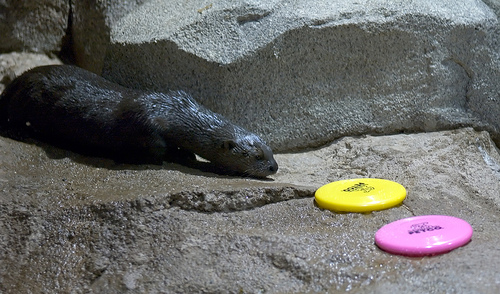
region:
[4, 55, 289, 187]
A sea otter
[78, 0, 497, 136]
A large boulder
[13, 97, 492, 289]
A large boulder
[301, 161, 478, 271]
A pair of frisbees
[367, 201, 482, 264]
A pink frisbee on the boulder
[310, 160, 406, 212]
A yellow frisbee on the boulder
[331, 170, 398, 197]
branding on the yellow frisbee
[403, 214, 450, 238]
branding on the pink frisbee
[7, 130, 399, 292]
some water on the boulder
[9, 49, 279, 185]
an otter examining some frisbees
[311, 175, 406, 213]
A yellow frisbee with dark writing on top.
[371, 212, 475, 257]
A pink frisbee with purple writing on top.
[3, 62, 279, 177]
Brown otter near a yellow frisbee.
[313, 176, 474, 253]
Yellow and pink frisbee with writing on top.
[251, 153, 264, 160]
Small eye of an otter.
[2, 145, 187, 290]
Large wet brown and gray rock under an otter.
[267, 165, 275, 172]
Black nostril on the side of an otters face.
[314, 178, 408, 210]
Bright yellow frisbee with dark writing on top.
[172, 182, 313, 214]
Large crack in the rock to the left of a yellow frisbee.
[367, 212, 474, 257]
Pink frisbee with purple writing on top.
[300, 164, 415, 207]
yellow plastic frisbee laying on ground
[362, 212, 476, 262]
pink plastic frisbee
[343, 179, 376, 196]
black writing on top of frisbee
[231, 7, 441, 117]
large grey boulder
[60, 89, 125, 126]
wet black fur on side of animal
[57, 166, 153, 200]
grey boulder covered in water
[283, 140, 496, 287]
two frisbees laying on boulder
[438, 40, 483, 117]
large crack in side of boulder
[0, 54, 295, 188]
black animal walking on grey rock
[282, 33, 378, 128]
porous grey rock face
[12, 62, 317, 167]
black wet sea otter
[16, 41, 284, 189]
sea otter in a zoo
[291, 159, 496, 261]
two frisbees on a large rock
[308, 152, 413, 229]
yellow frisbee on large grey rock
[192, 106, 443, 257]
sea otter looking at frisbees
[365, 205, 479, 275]
pink frisbee with purple lettering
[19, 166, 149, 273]
rock wet from sea otter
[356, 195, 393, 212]
light reflecting on frisbee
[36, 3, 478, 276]
large grey rocks in frisbee enclosure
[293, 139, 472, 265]
two frisbees for the sea otter to play with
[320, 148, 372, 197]
yellow frisbee on rocks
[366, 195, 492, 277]
pink frisbee on rocks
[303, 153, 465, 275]
round frisbees on rocks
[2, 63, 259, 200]
seal sleeping near frisbees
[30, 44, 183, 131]
seal has dark fur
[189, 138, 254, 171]
seal has black ears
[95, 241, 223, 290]
rocks are wet and grey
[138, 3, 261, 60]
lighter rocks above seal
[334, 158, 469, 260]
black writing on frisbees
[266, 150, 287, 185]
seal has black nose